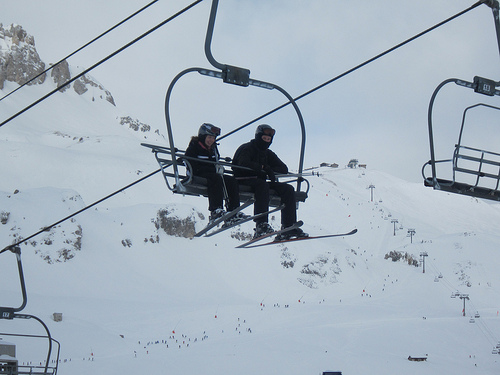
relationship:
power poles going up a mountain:
[348, 180, 478, 325] [1, 22, 496, 373]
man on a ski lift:
[231, 124, 310, 242] [137, 0, 307, 202]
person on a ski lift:
[182, 122, 247, 225] [137, 0, 307, 202]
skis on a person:
[197, 202, 277, 232] [182, 122, 250, 227]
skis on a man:
[235, 220, 359, 248] [231, 124, 310, 242]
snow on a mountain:
[2, 25, 499, 374] [1, 22, 496, 373]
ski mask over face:
[255, 122, 274, 150] [259, 132, 275, 144]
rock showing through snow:
[155, 212, 193, 247] [0, 80, 499, 372]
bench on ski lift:
[145, 130, 305, 204] [143, 1, 369, 252]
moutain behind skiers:
[20, 50, 180, 190] [171, 106, 349, 235]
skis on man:
[231, 208, 361, 248] [216, 92, 389, 289]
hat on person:
[198, 119, 224, 139] [182, 122, 250, 227]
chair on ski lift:
[1, 302, 60, 374] [145, 0, 353, 241]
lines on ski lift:
[2, 2, 207, 161] [140, 64, 315, 206]